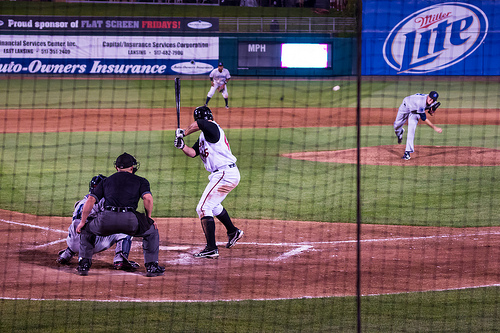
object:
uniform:
[189, 118, 241, 218]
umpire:
[73, 151, 167, 277]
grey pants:
[76, 205, 159, 262]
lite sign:
[383, 1, 491, 75]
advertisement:
[360, 0, 500, 76]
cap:
[111, 155, 140, 174]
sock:
[197, 214, 219, 254]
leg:
[194, 177, 236, 249]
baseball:
[331, 84, 342, 93]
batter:
[172, 104, 244, 261]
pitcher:
[391, 89, 444, 162]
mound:
[276, 142, 500, 169]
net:
[0, 0, 499, 333]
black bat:
[172, 76, 184, 149]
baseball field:
[0, 74, 499, 331]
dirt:
[215, 181, 238, 198]